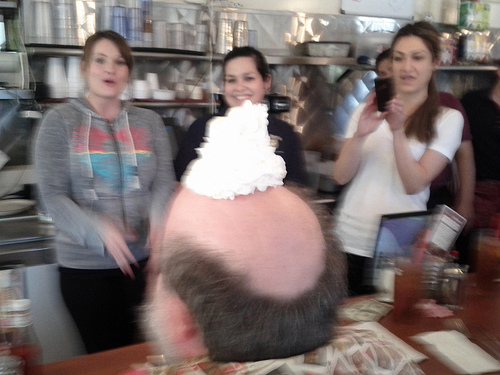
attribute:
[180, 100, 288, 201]
whipped cream — white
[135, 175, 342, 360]
head — bald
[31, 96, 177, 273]
hoodie — gray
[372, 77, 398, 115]
phone — black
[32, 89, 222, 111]
shelf — metal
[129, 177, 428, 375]
man — bald, goofy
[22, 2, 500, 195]
shelves — distant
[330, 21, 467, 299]
girl — photographing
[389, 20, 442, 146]
hair — brown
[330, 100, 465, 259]
shirt — white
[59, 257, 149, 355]
pants — dark, black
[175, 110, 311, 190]
shirt — black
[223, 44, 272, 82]
hair — dark